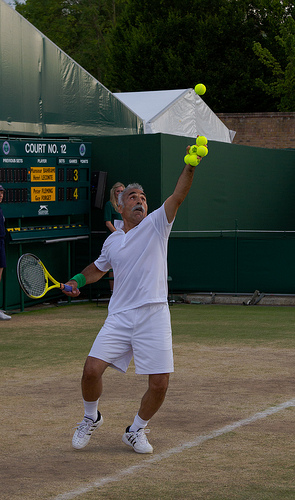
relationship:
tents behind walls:
[8, 18, 232, 154] [24, 136, 288, 290]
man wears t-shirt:
[61, 139, 204, 453] [86, 202, 181, 311]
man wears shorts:
[61, 139, 204, 453] [82, 304, 175, 377]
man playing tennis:
[61, 139, 204, 453] [12, 251, 78, 299]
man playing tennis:
[61, 139, 204, 453] [9, 59, 253, 489]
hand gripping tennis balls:
[182, 140, 206, 169] [184, 134, 209, 167]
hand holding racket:
[43, 269, 88, 305] [9, 244, 84, 300]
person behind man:
[105, 181, 125, 230] [61, 139, 204, 453]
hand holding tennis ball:
[182, 140, 206, 169] [197, 130, 211, 146]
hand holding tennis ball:
[182, 140, 206, 169] [194, 143, 209, 157]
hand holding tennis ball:
[182, 140, 206, 169] [188, 143, 197, 154]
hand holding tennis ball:
[182, 140, 206, 169] [184, 149, 199, 166]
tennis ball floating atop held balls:
[191, 82, 214, 100] [179, 135, 208, 166]